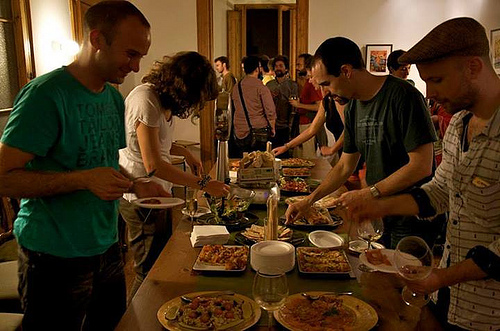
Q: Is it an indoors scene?
A: Yes, it is indoors.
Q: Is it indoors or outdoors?
A: It is indoors.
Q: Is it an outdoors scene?
A: No, it is indoors.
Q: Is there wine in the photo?
A: Yes, there is wine.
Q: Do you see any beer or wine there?
A: Yes, there is wine.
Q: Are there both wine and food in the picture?
A: Yes, there are both wine and food.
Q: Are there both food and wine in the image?
A: Yes, there are both wine and food.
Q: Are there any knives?
A: No, there are no knives.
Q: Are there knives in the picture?
A: No, there are no knives.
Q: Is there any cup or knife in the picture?
A: No, there are no knives or cups.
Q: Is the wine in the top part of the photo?
A: No, the wine is in the bottom of the image.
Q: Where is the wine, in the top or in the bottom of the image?
A: The wine is in the bottom of the image.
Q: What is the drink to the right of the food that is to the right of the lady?
A: The drink is wine.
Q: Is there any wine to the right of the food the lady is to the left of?
A: Yes, there is wine to the right of the food.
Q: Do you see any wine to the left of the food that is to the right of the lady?
A: No, the wine is to the right of the food.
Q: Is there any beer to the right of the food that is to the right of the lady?
A: No, there is wine to the right of the food.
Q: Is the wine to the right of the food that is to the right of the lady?
A: Yes, the wine is to the right of the food.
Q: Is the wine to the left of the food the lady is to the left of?
A: No, the wine is to the right of the food.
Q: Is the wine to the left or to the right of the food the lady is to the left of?
A: The wine is to the right of the food.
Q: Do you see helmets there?
A: No, there are no helmets.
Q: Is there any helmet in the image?
A: No, there are no helmets.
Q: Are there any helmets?
A: No, there are no helmets.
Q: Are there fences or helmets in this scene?
A: No, there are no helmets or fences.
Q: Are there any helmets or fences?
A: No, there are no helmets or fences.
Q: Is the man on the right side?
A: Yes, the man is on the right of the image.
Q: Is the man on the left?
A: No, the man is on the right of the image.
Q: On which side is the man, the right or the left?
A: The man is on the right of the image.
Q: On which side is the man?
A: The man is on the right of the image.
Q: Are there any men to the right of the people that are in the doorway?
A: Yes, there is a man to the right of the people.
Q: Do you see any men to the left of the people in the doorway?
A: No, the man is to the right of the people.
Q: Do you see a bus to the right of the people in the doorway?
A: No, there is a man to the right of the people.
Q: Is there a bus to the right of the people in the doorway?
A: No, there is a man to the right of the people.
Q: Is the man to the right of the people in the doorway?
A: Yes, the man is to the right of the people.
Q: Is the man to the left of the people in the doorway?
A: No, the man is to the right of the people.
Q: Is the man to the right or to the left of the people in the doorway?
A: The man is to the right of the people.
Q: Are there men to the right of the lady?
A: Yes, there is a man to the right of the lady.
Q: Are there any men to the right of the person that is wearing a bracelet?
A: Yes, there is a man to the right of the lady.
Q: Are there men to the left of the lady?
A: No, the man is to the right of the lady.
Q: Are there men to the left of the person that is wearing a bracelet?
A: No, the man is to the right of the lady.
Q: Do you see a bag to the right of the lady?
A: No, there is a man to the right of the lady.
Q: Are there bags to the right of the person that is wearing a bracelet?
A: No, there is a man to the right of the lady.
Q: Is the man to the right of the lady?
A: Yes, the man is to the right of the lady.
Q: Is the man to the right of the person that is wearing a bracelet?
A: Yes, the man is to the right of the lady.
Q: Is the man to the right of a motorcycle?
A: No, the man is to the right of the lady.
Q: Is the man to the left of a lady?
A: No, the man is to the right of a lady.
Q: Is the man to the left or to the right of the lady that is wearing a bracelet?
A: The man is to the right of the lady.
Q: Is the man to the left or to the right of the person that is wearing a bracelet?
A: The man is to the right of the lady.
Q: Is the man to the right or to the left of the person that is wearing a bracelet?
A: The man is to the right of the lady.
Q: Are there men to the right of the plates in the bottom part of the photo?
A: Yes, there is a man to the right of the plates.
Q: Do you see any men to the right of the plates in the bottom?
A: Yes, there is a man to the right of the plates.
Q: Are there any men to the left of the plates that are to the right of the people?
A: No, the man is to the right of the plates.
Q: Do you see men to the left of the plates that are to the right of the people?
A: No, the man is to the right of the plates.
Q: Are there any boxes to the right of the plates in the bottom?
A: No, there is a man to the right of the plates.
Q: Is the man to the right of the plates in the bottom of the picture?
A: Yes, the man is to the right of the plates.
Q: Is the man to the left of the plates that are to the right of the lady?
A: No, the man is to the right of the plates.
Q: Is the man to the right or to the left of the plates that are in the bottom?
A: The man is to the right of the plates.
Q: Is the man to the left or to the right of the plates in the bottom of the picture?
A: The man is to the right of the plates.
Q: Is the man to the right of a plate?
A: Yes, the man is to the right of a plate.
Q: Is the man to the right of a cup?
A: No, the man is to the right of a plate.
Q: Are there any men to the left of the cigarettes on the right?
A: Yes, there is a man to the left of the cigarettes.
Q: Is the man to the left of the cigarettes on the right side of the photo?
A: Yes, the man is to the left of the cigarettes.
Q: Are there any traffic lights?
A: No, there are no traffic lights.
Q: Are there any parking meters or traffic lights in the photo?
A: No, there are no traffic lights or parking meters.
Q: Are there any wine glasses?
A: Yes, there is a wine glass.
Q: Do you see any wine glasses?
A: Yes, there is a wine glass.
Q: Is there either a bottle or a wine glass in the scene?
A: Yes, there is a wine glass.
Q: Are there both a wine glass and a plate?
A: Yes, there are both a wine glass and a plate.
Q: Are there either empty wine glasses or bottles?
A: Yes, there is an empty wine glass.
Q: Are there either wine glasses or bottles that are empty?
A: Yes, the wine glass is empty.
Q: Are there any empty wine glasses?
A: Yes, there is an empty wine glass.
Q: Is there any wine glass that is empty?
A: Yes, there is a wine glass that is empty.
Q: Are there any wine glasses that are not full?
A: Yes, there is a empty wine glass.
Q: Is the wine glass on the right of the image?
A: Yes, the wine glass is on the right of the image.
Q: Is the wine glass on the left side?
A: No, the wine glass is on the right of the image.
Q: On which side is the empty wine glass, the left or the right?
A: The wineglass is on the right of the image.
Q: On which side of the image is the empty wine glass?
A: The wine glass is on the right of the image.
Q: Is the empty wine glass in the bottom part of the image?
A: Yes, the wine glass is in the bottom of the image.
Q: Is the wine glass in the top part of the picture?
A: No, the wine glass is in the bottom of the image.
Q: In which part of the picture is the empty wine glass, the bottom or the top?
A: The wineglass is in the bottom of the image.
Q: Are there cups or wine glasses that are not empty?
A: No, there is a wine glass but it is empty.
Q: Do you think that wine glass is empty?
A: Yes, the wine glass is empty.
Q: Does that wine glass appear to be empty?
A: Yes, the wine glass is empty.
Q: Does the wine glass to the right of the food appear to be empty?
A: Yes, the wine glass is empty.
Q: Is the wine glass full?
A: No, the wine glass is empty.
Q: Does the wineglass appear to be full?
A: No, the wineglass is empty.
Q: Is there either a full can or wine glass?
A: No, there is a wine glass but it is empty.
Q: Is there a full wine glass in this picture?
A: No, there is a wine glass but it is empty.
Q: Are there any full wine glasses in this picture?
A: No, there is a wine glass but it is empty.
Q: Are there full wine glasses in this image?
A: No, there is a wine glass but it is empty.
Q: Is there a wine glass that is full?
A: No, there is a wine glass but it is empty.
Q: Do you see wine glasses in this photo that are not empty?
A: No, there is a wine glass but it is empty.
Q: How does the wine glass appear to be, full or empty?
A: The wine glass is empty.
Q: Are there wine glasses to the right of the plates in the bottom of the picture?
A: Yes, there is a wine glass to the right of the plates.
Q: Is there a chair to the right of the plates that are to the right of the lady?
A: No, there is a wine glass to the right of the plates.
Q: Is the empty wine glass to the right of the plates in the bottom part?
A: Yes, the wine glass is to the right of the plates.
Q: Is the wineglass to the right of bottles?
A: No, the wineglass is to the right of the plates.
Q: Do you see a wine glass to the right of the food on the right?
A: Yes, there is a wine glass to the right of the food.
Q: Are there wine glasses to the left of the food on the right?
A: No, the wine glass is to the right of the food.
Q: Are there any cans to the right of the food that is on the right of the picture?
A: No, there is a wine glass to the right of the food.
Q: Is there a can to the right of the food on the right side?
A: No, there is a wine glass to the right of the food.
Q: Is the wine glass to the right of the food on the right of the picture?
A: Yes, the wine glass is to the right of the food.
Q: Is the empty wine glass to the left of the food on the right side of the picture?
A: No, the wine glass is to the right of the food.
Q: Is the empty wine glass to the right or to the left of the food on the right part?
A: The wine glass is to the right of the food.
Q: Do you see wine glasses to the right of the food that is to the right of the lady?
A: Yes, there is a wine glass to the right of the food.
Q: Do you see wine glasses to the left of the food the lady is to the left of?
A: No, the wine glass is to the right of the food.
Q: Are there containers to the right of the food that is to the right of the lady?
A: No, there is a wine glass to the right of the food.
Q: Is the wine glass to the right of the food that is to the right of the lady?
A: Yes, the wine glass is to the right of the food.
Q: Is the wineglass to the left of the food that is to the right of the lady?
A: No, the wineglass is to the right of the food.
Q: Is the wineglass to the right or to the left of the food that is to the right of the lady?
A: The wineglass is to the right of the food.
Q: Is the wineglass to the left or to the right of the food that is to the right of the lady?
A: The wineglass is to the right of the food.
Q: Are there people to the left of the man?
A: Yes, there are people to the left of the man.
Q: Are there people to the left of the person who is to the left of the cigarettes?
A: Yes, there are people to the left of the man.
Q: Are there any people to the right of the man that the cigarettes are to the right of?
A: No, the people are to the left of the man.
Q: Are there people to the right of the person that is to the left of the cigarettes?
A: No, the people are to the left of the man.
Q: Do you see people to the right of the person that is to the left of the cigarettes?
A: No, the people are to the left of the man.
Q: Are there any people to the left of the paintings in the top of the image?
A: Yes, there are people to the left of the paintings.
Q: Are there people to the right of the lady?
A: Yes, there are people to the right of the lady.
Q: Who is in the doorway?
A: The people are in the doorway.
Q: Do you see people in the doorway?
A: Yes, there are people in the doorway.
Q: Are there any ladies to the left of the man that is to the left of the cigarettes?
A: Yes, there is a lady to the left of the man.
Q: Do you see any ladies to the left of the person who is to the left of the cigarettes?
A: Yes, there is a lady to the left of the man.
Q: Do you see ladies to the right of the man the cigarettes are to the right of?
A: No, the lady is to the left of the man.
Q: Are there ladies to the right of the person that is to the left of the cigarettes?
A: No, the lady is to the left of the man.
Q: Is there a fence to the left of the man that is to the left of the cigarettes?
A: No, there is a lady to the left of the man.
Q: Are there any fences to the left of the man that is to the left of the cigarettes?
A: No, there is a lady to the left of the man.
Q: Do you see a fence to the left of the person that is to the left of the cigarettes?
A: No, there is a lady to the left of the man.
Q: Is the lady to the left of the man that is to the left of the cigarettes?
A: Yes, the lady is to the left of the man.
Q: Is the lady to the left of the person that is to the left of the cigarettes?
A: Yes, the lady is to the left of the man.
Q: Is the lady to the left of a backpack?
A: No, the lady is to the left of the man.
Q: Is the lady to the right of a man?
A: No, the lady is to the left of a man.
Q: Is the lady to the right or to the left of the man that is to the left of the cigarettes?
A: The lady is to the left of the man.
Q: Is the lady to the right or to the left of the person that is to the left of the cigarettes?
A: The lady is to the left of the man.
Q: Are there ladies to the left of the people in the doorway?
A: Yes, there is a lady to the left of the people.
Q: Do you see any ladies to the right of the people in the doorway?
A: No, the lady is to the left of the people.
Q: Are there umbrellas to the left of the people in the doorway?
A: No, there is a lady to the left of the people.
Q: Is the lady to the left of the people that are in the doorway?
A: Yes, the lady is to the left of the people.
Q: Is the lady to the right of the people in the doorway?
A: No, the lady is to the left of the people.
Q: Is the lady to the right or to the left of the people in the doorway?
A: The lady is to the left of the people.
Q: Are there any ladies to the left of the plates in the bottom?
A: Yes, there is a lady to the left of the plates.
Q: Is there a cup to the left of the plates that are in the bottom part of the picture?
A: No, there is a lady to the left of the plates.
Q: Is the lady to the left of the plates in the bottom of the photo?
A: Yes, the lady is to the left of the plates.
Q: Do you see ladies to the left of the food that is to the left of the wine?
A: Yes, there is a lady to the left of the food.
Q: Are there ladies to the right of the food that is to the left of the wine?
A: No, the lady is to the left of the food.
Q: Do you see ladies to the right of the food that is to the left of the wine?
A: No, the lady is to the left of the food.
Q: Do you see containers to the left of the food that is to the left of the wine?
A: No, there is a lady to the left of the food.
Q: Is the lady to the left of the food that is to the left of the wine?
A: Yes, the lady is to the left of the food.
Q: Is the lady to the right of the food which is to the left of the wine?
A: No, the lady is to the left of the food.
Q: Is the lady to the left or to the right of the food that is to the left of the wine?
A: The lady is to the left of the food.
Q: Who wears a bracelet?
A: The lady wears a bracelet.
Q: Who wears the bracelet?
A: The lady wears a bracelet.